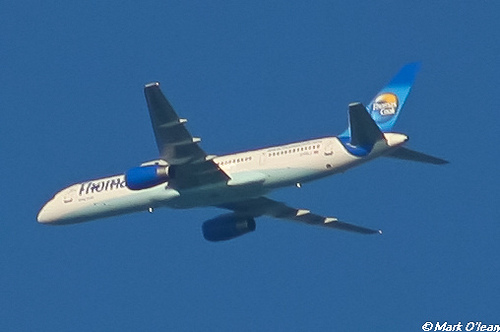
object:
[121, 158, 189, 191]
engine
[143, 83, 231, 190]
wing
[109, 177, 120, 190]
words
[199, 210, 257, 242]
engine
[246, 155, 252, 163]
windows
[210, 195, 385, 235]
wing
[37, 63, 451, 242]
plane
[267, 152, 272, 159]
window